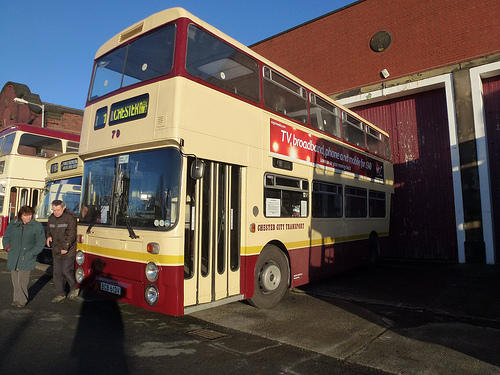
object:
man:
[44, 199, 80, 304]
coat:
[45, 209, 77, 256]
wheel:
[247, 242, 292, 310]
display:
[102, 99, 146, 123]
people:
[1, 204, 46, 310]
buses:
[30, 151, 86, 265]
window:
[77, 143, 183, 233]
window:
[260, 170, 311, 219]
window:
[186, 23, 262, 104]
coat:
[1, 219, 47, 271]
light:
[75, 251, 85, 266]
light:
[74, 267, 84, 284]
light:
[144, 262, 160, 283]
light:
[144, 282, 161, 305]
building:
[393, 0, 495, 275]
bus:
[74, 5, 396, 318]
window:
[262, 66, 310, 123]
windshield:
[71, 16, 191, 110]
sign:
[279, 122, 374, 173]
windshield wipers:
[84, 217, 100, 234]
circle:
[369, 28, 395, 53]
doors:
[182, 152, 242, 311]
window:
[310, 94, 341, 136]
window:
[310, 177, 343, 219]